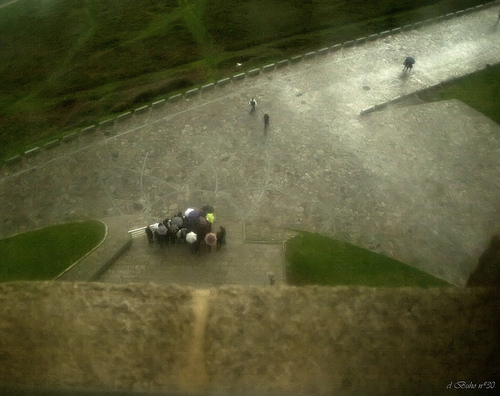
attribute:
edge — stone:
[6, 274, 495, 385]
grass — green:
[1, 1, 262, 85]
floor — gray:
[81, 79, 499, 246]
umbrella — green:
[203, 209, 217, 228]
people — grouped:
[138, 202, 231, 257]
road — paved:
[6, 5, 498, 216]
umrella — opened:
[182, 230, 201, 244]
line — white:
[87, 99, 210, 140]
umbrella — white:
[181, 206, 195, 218]